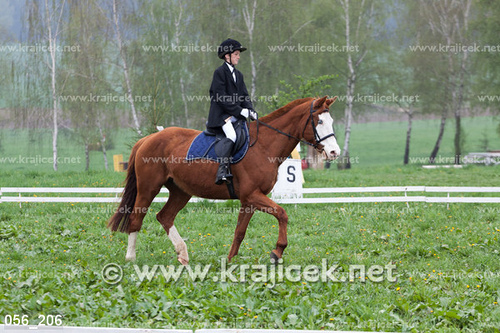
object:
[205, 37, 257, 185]
person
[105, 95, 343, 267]
horse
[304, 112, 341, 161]
face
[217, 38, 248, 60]
helmet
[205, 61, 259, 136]
coat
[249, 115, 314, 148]
rein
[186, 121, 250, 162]
blanket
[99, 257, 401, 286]
website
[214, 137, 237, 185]
boot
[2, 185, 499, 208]
fence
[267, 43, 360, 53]
website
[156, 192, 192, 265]
rear leg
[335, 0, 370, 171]
tree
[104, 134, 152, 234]
tail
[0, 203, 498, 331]
field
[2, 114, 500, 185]
field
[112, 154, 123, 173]
object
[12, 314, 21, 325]
five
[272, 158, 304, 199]
sign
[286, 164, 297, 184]
s